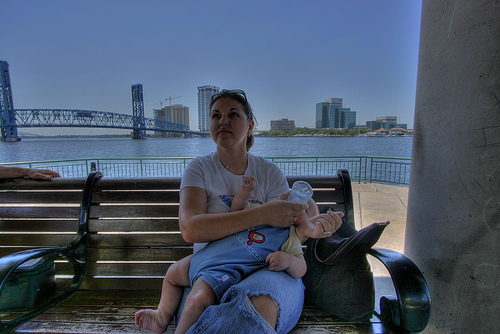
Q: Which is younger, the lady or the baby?
A: The baby is younger than the lady.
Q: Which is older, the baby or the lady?
A: The lady is older than the baby.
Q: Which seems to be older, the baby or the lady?
A: The lady is older than the baby.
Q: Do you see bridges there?
A: Yes, there is a bridge.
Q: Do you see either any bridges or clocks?
A: Yes, there is a bridge.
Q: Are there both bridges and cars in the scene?
A: No, there is a bridge but no cars.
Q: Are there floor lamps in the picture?
A: No, there are no floor lamps.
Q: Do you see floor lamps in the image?
A: No, there are no floor lamps.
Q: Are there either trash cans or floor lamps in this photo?
A: No, there are no floor lamps or trash cans.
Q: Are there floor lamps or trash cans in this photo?
A: No, there are no floor lamps or trash cans.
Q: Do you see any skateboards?
A: No, there are no skateboards.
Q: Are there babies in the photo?
A: Yes, there is a baby.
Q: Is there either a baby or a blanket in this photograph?
A: Yes, there is a baby.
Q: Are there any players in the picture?
A: No, there are no players.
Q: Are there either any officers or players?
A: No, there are no players or officers.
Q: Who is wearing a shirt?
A: The baby is wearing a shirt.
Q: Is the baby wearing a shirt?
A: Yes, the baby is wearing a shirt.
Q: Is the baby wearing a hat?
A: No, the baby is wearing a shirt.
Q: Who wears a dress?
A: The baby wears a dress.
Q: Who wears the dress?
A: The baby wears a dress.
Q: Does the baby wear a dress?
A: Yes, the baby wears a dress.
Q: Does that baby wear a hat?
A: No, the baby wears a dress.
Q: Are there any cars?
A: No, there are no cars.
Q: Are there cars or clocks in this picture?
A: No, there are no cars or clocks.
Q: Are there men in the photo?
A: No, there are no men.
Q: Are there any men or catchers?
A: No, there are no men or catchers.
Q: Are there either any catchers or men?
A: No, there are no men or catchers.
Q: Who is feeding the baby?
A: The lady is feeding the baby.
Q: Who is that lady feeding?
A: The lady is feeding the baby.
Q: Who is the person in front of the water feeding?
A: The lady is feeding the baby.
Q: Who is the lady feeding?
A: The lady is feeding the baby.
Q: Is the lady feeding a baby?
A: Yes, the lady is feeding a baby.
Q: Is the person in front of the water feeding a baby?
A: Yes, the lady is feeding a baby.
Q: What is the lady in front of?
A: The lady is in front of the water.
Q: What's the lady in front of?
A: The lady is in front of the water.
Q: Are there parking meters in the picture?
A: No, there are no parking meters.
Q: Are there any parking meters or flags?
A: No, there are no parking meters or flags.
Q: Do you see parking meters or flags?
A: No, there are no parking meters or flags.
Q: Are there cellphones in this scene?
A: No, there are no cellphones.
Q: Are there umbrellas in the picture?
A: No, there are no umbrellas.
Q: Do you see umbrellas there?
A: No, there are no umbrellas.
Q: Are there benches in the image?
A: Yes, there is a bench.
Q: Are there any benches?
A: Yes, there is a bench.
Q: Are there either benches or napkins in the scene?
A: Yes, there is a bench.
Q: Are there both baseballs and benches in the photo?
A: No, there is a bench but no baseballs.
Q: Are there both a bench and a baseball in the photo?
A: No, there is a bench but no baseballs.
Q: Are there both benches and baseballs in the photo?
A: No, there is a bench but no baseballs.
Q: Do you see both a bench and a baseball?
A: No, there is a bench but no baseballs.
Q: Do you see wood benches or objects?
A: Yes, there is a wood bench.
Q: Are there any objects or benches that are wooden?
A: Yes, the bench is wooden.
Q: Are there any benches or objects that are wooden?
A: Yes, the bench is wooden.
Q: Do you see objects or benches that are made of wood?
A: Yes, the bench is made of wood.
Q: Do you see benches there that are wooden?
A: Yes, there is a wood bench.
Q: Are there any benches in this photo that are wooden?
A: Yes, there is a bench that is wooden.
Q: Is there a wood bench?
A: Yes, there is a bench that is made of wood.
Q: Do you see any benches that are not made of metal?
A: Yes, there is a bench that is made of wood.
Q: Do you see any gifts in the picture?
A: No, there are no gifts.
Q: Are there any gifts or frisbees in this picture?
A: No, there are no gifts or frisbees.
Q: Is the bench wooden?
A: Yes, the bench is wooden.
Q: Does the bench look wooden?
A: Yes, the bench is wooden.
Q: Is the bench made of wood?
A: Yes, the bench is made of wood.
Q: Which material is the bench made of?
A: The bench is made of wood.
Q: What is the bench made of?
A: The bench is made of wood.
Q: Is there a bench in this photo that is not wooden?
A: No, there is a bench but it is wooden.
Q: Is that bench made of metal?
A: No, the bench is made of wood.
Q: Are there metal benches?
A: No, there is a bench but it is made of wood.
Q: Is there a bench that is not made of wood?
A: No, there is a bench but it is made of wood.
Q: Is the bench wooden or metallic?
A: The bench is wooden.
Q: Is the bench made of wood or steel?
A: The bench is made of wood.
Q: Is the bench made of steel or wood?
A: The bench is made of wood.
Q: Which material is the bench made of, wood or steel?
A: The bench is made of wood.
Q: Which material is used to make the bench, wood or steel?
A: The bench is made of wood.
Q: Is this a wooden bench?
A: Yes, this is a wooden bench.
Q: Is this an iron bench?
A: No, this is a wooden bench.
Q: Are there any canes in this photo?
A: No, there are no canes.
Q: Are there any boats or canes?
A: No, there are no canes or boats.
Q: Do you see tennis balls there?
A: No, there are no tennis balls.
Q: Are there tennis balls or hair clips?
A: No, there are no tennis balls or hair clips.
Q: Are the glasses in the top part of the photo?
A: Yes, the glasses are in the top of the image.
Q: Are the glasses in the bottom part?
A: No, the glasses are in the top of the image.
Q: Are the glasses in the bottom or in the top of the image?
A: The glasses are in the top of the image.